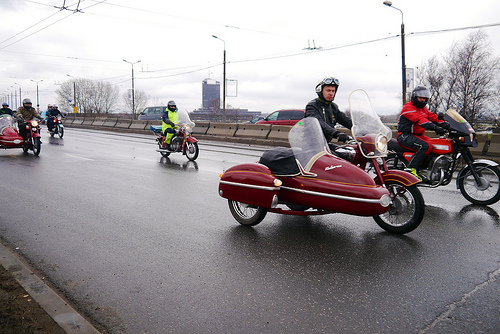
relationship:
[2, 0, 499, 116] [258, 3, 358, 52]
clouds in sky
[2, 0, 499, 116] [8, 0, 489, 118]
clouds in sky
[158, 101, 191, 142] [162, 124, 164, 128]
person wearing yellow raincoat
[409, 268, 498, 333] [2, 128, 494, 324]
road in road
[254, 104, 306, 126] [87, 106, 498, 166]
car on side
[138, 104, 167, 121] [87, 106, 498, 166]
car on side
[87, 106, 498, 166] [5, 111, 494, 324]
side of highway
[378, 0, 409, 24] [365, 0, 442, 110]
light on pole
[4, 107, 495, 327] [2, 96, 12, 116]
street of person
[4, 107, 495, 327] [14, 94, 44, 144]
street of person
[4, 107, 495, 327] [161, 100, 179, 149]
street of person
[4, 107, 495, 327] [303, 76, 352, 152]
street of person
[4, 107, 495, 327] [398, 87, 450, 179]
street of person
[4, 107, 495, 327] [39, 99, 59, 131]
street of person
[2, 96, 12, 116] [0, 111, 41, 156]
person on bikes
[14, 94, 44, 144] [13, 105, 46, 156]
person on motorcycle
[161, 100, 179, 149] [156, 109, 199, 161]
person on bike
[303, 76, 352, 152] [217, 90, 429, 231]
person on motorcycle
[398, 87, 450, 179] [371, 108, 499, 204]
person on bike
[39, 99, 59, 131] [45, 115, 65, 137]
person on bike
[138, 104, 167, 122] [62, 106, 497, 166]
car on side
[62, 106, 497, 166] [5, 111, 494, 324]
side of highway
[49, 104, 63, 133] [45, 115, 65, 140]
person on bike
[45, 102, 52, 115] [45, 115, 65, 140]
person on bike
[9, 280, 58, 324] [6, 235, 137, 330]
dirt on side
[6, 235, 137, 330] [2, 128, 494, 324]
side of road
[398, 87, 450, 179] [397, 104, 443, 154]
person wearing outfit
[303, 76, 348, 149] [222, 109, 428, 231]
person riding bike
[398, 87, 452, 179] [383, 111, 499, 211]
person riding bike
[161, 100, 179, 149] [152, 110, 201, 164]
person riding bike